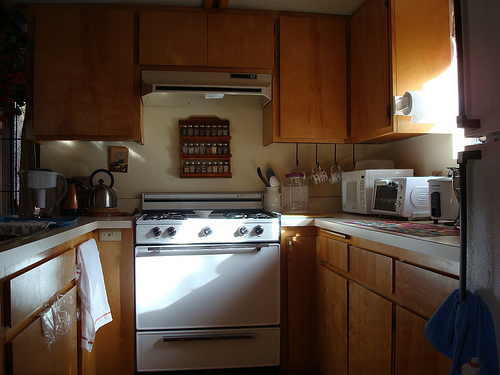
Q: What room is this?
A: It is a kitchen.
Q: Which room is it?
A: It is a kitchen.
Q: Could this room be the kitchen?
A: Yes, it is the kitchen.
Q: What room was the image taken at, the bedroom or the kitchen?
A: It was taken at the kitchen.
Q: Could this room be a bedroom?
A: No, it is a kitchen.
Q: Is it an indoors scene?
A: Yes, it is indoors.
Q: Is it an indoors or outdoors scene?
A: It is indoors.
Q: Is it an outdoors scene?
A: No, it is indoors.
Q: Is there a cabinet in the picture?
A: Yes, there is a cabinet.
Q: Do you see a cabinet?
A: Yes, there is a cabinet.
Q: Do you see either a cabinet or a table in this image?
A: Yes, there is a cabinet.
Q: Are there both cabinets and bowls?
A: No, there is a cabinet but no bowls.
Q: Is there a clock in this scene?
A: No, there are no clocks.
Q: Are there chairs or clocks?
A: No, there are no clocks or chairs.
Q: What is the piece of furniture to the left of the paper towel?
A: The piece of furniture is a cabinet.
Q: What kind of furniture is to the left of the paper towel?
A: The piece of furniture is a cabinet.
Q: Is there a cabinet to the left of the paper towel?
A: Yes, there is a cabinet to the left of the paper towel.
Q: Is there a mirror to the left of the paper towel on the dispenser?
A: No, there is a cabinet to the left of the paper towel.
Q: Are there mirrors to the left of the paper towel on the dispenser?
A: No, there is a cabinet to the left of the paper towel.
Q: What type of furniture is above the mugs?
A: The piece of furniture is a cabinet.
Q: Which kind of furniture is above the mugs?
A: The piece of furniture is a cabinet.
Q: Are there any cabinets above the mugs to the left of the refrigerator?
A: Yes, there is a cabinet above the mugs.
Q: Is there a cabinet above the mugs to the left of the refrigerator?
A: Yes, there is a cabinet above the mugs.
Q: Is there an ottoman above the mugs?
A: No, there is a cabinet above the mugs.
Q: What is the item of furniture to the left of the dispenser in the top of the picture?
A: The piece of furniture is a cabinet.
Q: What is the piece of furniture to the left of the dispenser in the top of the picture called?
A: The piece of furniture is a cabinet.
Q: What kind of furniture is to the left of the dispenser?
A: The piece of furniture is a cabinet.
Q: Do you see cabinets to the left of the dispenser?
A: Yes, there is a cabinet to the left of the dispenser.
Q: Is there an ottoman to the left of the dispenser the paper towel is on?
A: No, there is a cabinet to the left of the dispenser.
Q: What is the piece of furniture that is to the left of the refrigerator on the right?
A: The piece of furniture is a cabinet.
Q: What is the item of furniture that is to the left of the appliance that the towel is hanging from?
A: The piece of furniture is a cabinet.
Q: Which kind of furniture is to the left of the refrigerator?
A: The piece of furniture is a cabinet.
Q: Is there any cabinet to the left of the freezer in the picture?
A: Yes, there is a cabinet to the left of the freezer.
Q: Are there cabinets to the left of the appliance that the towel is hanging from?
A: Yes, there is a cabinet to the left of the freezer.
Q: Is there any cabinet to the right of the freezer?
A: No, the cabinet is to the left of the freezer.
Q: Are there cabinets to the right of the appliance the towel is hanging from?
A: No, the cabinet is to the left of the freezer.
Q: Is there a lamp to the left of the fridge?
A: No, there is a cabinet to the left of the fridge.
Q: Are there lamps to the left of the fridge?
A: No, there is a cabinet to the left of the fridge.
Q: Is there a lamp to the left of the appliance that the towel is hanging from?
A: No, there is a cabinet to the left of the fridge.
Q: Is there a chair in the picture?
A: No, there are no chairs.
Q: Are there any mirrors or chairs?
A: No, there are no chairs or mirrors.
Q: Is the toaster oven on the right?
A: Yes, the toaster oven is on the right of the image.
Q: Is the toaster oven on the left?
A: No, the toaster oven is on the right of the image.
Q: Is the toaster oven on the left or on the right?
A: The toaster oven is on the right of the image.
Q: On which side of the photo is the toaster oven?
A: The toaster oven is on the right of the image.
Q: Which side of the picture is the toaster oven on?
A: The toaster oven is on the right of the image.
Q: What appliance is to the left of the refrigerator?
A: The appliance is a toaster oven.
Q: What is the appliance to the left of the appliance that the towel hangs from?
A: The appliance is a toaster oven.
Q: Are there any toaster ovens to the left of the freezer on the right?
A: Yes, there is a toaster oven to the left of the freezer.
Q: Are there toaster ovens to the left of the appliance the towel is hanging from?
A: Yes, there is a toaster oven to the left of the freezer.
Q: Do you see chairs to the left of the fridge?
A: No, there is a toaster oven to the left of the fridge.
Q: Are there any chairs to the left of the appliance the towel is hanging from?
A: No, there is a toaster oven to the left of the fridge.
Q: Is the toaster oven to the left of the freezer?
A: Yes, the toaster oven is to the left of the freezer.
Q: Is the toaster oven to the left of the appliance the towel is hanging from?
A: Yes, the toaster oven is to the left of the freezer.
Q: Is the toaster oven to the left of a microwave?
A: No, the toaster oven is to the left of the freezer.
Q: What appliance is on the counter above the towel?
A: The appliance is a toaster oven.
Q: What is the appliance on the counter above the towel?
A: The appliance is a toaster oven.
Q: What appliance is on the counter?
A: The appliance is a toaster oven.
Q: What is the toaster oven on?
A: The toaster oven is on the counter.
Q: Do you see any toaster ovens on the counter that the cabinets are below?
A: Yes, there is a toaster oven on the counter.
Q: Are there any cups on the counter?
A: No, there is a toaster oven on the counter.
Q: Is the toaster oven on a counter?
A: Yes, the toaster oven is on a counter.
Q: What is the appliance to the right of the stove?
A: The appliance is a toaster oven.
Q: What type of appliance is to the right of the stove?
A: The appliance is a toaster oven.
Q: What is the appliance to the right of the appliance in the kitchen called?
A: The appliance is a toaster oven.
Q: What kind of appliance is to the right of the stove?
A: The appliance is a toaster oven.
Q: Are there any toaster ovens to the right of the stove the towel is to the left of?
A: Yes, there is a toaster oven to the right of the stove.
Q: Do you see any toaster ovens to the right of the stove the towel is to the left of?
A: Yes, there is a toaster oven to the right of the stove.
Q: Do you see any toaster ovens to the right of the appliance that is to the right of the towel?
A: Yes, there is a toaster oven to the right of the stove.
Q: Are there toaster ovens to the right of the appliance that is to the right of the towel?
A: Yes, there is a toaster oven to the right of the stove.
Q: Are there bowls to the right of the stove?
A: No, there is a toaster oven to the right of the stove.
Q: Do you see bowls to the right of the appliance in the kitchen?
A: No, there is a toaster oven to the right of the stove.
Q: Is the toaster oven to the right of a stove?
A: Yes, the toaster oven is to the right of a stove.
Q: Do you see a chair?
A: No, there are no chairs.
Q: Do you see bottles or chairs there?
A: No, there are no chairs or bottles.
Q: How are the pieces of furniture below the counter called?
A: The pieces of furniture are cabinets.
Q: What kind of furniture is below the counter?
A: The pieces of furniture are cabinets.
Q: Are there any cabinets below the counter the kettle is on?
A: Yes, there are cabinets below the counter.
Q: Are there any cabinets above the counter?
A: No, the cabinets are below the counter.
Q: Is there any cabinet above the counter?
A: No, the cabinets are below the counter.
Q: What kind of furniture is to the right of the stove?
A: The pieces of furniture are cabinets.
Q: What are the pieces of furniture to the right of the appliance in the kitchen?
A: The pieces of furniture are cabinets.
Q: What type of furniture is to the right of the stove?
A: The pieces of furniture are cabinets.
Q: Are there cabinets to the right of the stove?
A: Yes, there are cabinets to the right of the stove.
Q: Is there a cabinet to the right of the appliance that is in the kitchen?
A: Yes, there are cabinets to the right of the stove.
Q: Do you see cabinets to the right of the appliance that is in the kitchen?
A: Yes, there are cabinets to the right of the stove.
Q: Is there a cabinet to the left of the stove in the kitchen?
A: No, the cabinets are to the right of the stove.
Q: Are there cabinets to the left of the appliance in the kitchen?
A: No, the cabinets are to the right of the stove.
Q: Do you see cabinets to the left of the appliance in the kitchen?
A: No, the cabinets are to the right of the stove.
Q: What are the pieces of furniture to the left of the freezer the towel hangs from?
A: The pieces of furniture are cabinets.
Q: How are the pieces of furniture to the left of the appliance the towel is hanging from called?
A: The pieces of furniture are cabinets.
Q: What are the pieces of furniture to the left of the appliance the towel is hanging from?
A: The pieces of furniture are cabinets.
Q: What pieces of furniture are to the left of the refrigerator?
A: The pieces of furniture are cabinets.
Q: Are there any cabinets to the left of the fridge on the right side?
A: Yes, there are cabinets to the left of the fridge.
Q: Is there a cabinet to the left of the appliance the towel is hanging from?
A: Yes, there are cabinets to the left of the fridge.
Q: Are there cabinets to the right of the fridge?
A: No, the cabinets are to the left of the fridge.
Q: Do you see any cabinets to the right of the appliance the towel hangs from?
A: No, the cabinets are to the left of the fridge.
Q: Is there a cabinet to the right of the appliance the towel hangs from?
A: No, the cabinets are to the left of the fridge.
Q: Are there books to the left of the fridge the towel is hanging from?
A: No, there are cabinets to the left of the freezer.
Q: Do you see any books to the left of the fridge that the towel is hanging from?
A: No, there are cabinets to the left of the freezer.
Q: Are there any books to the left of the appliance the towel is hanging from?
A: No, there are cabinets to the left of the freezer.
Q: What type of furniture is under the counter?
A: The pieces of furniture are cabinets.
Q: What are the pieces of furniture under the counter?
A: The pieces of furniture are cabinets.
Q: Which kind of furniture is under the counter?
A: The pieces of furniture are cabinets.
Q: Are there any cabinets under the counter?
A: Yes, there are cabinets under the counter.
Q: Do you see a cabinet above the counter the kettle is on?
A: No, the cabinets are under the counter.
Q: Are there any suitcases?
A: No, there are no suitcases.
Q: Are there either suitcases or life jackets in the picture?
A: No, there are no suitcases or life jackets.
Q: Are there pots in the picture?
A: No, there are no pots.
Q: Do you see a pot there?
A: No, there are no pots.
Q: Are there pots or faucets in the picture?
A: No, there are no pots or faucets.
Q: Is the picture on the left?
A: Yes, the picture is on the left of the image.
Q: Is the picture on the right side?
A: No, the picture is on the left of the image.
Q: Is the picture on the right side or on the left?
A: The picture is on the left of the image.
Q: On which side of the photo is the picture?
A: The picture is on the left of the image.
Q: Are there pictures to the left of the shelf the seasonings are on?
A: Yes, there is a picture to the left of the shelf.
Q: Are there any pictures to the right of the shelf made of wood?
A: No, the picture is to the left of the shelf.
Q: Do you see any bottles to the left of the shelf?
A: No, there is a picture to the left of the shelf.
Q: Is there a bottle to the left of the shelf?
A: No, there is a picture to the left of the shelf.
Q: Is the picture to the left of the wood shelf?
A: Yes, the picture is to the left of the shelf.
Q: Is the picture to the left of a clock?
A: No, the picture is to the left of the shelf.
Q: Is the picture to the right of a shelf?
A: No, the picture is to the left of a shelf.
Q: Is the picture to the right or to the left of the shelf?
A: The picture is to the left of the shelf.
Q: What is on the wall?
A: The picture is on the wall.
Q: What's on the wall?
A: The picture is on the wall.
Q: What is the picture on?
A: The picture is on the wall.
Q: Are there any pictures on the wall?
A: Yes, there is a picture on the wall.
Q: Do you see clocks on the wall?
A: No, there is a picture on the wall.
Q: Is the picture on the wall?
A: Yes, the picture is on the wall.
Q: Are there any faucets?
A: No, there are no faucets.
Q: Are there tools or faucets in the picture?
A: No, there are no faucets or tools.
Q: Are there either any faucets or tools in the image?
A: No, there are no faucets or tools.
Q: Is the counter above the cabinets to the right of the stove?
A: Yes, the counter is above the cabinets.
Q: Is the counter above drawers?
A: No, the counter is above the cabinets.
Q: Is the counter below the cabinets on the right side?
A: No, the counter is above the cabinets.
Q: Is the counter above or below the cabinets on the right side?
A: The counter is above the cabinets.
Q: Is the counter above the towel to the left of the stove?
A: Yes, the counter is above the towel.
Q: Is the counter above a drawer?
A: No, the counter is above the towel.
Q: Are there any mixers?
A: No, there are no mixers.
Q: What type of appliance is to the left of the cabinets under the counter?
A: The appliance is a stove.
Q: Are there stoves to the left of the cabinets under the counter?
A: Yes, there is a stove to the left of the cabinets.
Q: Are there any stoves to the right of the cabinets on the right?
A: No, the stove is to the left of the cabinets.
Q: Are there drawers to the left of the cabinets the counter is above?
A: No, there is a stove to the left of the cabinets.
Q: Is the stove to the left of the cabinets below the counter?
A: Yes, the stove is to the left of the cabinets.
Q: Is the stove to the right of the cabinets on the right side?
A: No, the stove is to the left of the cabinets.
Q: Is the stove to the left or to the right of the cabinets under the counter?
A: The stove is to the left of the cabinets.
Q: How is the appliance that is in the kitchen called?
A: The appliance is a stove.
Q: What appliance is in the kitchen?
A: The appliance is a stove.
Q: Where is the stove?
A: The stove is in the kitchen.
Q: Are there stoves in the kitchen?
A: Yes, there is a stove in the kitchen.